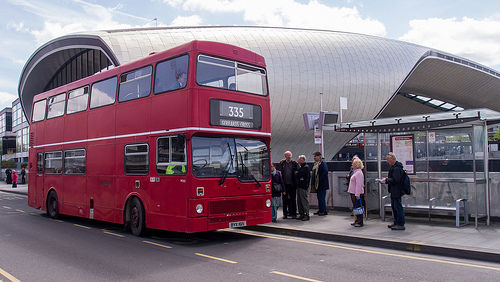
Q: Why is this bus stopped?
A: For pickup.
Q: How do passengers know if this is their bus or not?
A: The route number.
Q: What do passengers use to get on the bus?
A: Steps.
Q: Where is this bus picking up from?
A: A terminal.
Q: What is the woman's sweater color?
A: Pink.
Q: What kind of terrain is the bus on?
A: Flat.